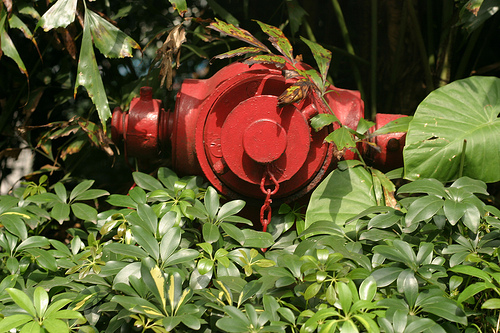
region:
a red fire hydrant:
[107, 52, 417, 239]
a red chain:
[256, 171, 276, 231]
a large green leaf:
[399, 76, 499, 184]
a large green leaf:
[300, 164, 395, 232]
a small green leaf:
[396, 176, 444, 197]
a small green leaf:
[403, 196, 440, 229]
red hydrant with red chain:
[95, 52, 409, 257]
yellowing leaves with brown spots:
[212, 15, 334, 106]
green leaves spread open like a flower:
[3, 278, 84, 330]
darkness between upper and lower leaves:
[7, 25, 162, 206]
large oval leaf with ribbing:
[400, 70, 495, 197]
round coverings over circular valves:
[190, 65, 335, 205]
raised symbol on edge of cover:
[201, 120, 226, 165]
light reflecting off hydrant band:
[130, 91, 160, 141]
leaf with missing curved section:
[70, 16, 113, 134]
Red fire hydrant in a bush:
[114, 52, 415, 198]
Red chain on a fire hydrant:
[255, 193, 275, 235]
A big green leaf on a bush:
[400, 72, 498, 187]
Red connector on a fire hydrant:
[100, 88, 173, 149]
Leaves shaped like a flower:
[6, 284, 81, 331]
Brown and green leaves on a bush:
[211, 15, 361, 159]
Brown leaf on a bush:
[157, 25, 189, 90]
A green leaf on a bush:
[217, 195, 243, 215]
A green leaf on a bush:
[404, 195, 441, 222]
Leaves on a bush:
[3, 281, 85, 331]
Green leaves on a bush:
[16, 171, 112, 242]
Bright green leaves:
[101, 158, 346, 320]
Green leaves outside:
[21, 166, 351, 320]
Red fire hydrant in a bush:
[91, 48, 455, 241]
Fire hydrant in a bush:
[103, 35, 454, 235]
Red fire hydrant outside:
[101, 43, 439, 246]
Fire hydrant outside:
[81, 36, 428, 236]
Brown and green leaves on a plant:
[213, 10, 432, 188]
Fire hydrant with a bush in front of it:
[101, 38, 461, 242]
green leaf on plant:
[441, 196, 464, 226]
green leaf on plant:
[456, 199, 481, 232]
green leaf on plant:
[403, 194, 442, 222]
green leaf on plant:
[396, 178, 452, 198]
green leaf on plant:
[401, 274, 420, 306]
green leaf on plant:
[368, 264, 398, 291]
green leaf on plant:
[367, 245, 408, 267]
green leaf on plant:
[334, 280, 351, 316]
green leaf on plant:
[216, 196, 243, 221]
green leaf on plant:
[176, 308, 203, 327]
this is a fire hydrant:
[94, 52, 446, 208]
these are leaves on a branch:
[271, 240, 320, 306]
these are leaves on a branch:
[354, 230, 446, 304]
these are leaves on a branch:
[89, 225, 196, 300]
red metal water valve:
[100, 50, 442, 235]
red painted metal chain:
[241, 169, 294, 235]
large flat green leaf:
[402, 69, 498, 197]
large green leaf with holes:
[399, 66, 499, 187]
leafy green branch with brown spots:
[197, 15, 386, 181]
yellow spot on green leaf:
[146, 260, 168, 321]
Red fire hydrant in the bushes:
[124, 48, 423, 203]